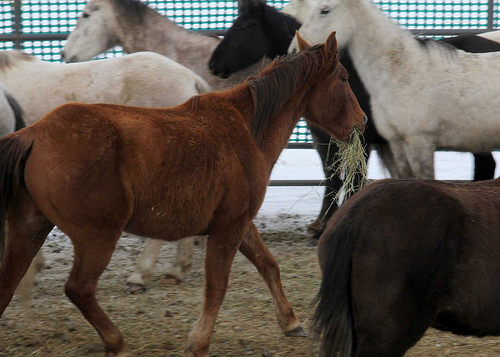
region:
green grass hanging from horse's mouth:
[332, 137, 373, 183]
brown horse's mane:
[237, 55, 323, 114]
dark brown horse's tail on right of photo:
[321, 199, 363, 354]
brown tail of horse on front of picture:
[4, 128, 28, 307]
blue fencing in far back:
[179, 2, 247, 38]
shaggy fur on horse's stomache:
[141, 117, 233, 222]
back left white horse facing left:
[48, 1, 163, 81]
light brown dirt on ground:
[136, 287, 176, 337]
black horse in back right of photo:
[203, 4, 288, 102]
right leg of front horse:
[198, 227, 265, 354]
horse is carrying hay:
[330, 98, 391, 191]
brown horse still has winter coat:
[91, 85, 308, 252]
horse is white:
[24, 43, 216, 116]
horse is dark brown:
[195, 1, 299, 74]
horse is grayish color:
[344, 4, 494, 118]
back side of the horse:
[321, 160, 494, 351]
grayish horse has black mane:
[404, 24, 474, 73]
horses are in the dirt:
[45, 210, 242, 355]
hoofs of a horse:
[115, 255, 204, 296]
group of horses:
[5, 4, 468, 334]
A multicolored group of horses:
[12, 5, 492, 348]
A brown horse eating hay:
[15, 30, 397, 354]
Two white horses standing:
[0, 2, 234, 180]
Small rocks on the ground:
[127, 287, 181, 327]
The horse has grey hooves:
[281, 320, 308, 346]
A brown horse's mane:
[224, 51, 334, 115]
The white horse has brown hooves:
[119, 277, 145, 297]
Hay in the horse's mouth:
[327, 121, 377, 191]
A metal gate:
[2, 0, 471, 191]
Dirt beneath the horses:
[262, 220, 331, 312]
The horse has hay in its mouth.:
[324, 120, 389, 208]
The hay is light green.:
[323, 127, 373, 215]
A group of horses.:
[1, 0, 496, 353]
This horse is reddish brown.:
[86, 26, 386, 220]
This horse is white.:
[278, 1, 398, 65]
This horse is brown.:
[318, 175, 495, 355]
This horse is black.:
[201, 2, 288, 79]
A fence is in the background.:
[1, 1, 499, 203]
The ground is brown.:
[133, 297, 173, 353]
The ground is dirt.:
[131, 293, 178, 353]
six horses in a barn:
[0, 1, 499, 354]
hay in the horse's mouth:
[325, 123, 368, 204]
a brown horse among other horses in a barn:
[0, 28, 367, 355]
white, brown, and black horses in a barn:
[0, 0, 498, 355]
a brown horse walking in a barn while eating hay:
[0, 29, 368, 355]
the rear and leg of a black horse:
[306, 176, 498, 355]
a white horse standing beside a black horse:
[287, 0, 498, 178]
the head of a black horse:
[207, 0, 260, 80]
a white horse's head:
[62, 0, 125, 62]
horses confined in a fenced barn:
[0, 1, 498, 355]